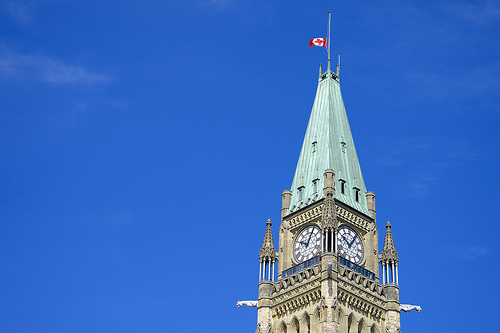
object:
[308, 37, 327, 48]
flag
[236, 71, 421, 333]
structure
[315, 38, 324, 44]
cross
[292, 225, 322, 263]
clock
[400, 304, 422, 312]
gargoyle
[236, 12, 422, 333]
building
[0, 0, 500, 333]
sky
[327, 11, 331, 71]
pole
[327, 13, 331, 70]
flagpole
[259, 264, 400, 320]
decoration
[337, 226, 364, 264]
clock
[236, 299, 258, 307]
decorative piece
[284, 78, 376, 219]
roof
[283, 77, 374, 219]
cap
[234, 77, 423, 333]
tower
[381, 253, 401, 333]
column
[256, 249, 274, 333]
column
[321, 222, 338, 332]
column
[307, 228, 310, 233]
numeral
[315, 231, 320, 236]
numeral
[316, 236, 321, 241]
numeral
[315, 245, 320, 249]
numeral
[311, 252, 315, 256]
numeral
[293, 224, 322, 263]
face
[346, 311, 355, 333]
window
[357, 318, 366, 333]
window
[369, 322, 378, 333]
window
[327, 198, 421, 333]
side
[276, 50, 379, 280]
top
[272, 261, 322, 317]
trim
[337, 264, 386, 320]
trim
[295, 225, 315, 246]
10:05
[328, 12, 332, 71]
slat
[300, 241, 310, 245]
hands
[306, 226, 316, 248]
hands